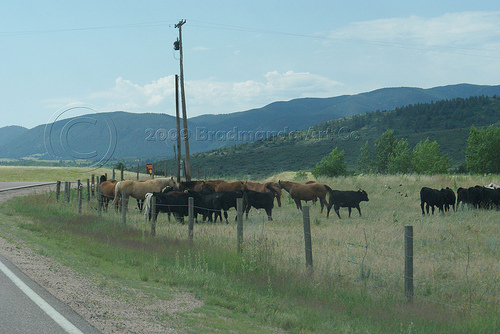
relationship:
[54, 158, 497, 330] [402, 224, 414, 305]
fence has pole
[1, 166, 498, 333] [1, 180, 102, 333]
grass next to road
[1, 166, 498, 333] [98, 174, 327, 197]
pasture has horse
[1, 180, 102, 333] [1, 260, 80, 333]
road has mark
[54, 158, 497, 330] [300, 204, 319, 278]
fence has wood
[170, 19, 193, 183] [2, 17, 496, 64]
post has wire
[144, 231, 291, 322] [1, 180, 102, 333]
plants next road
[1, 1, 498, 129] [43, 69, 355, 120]
sky has cloud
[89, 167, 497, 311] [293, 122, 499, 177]
pasture has trees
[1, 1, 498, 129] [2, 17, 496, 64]
sky has wire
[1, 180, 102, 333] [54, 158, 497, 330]
road next to field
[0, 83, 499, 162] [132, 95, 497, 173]
mountains has trees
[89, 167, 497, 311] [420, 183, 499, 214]
pasture has cows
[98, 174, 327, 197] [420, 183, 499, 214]
horse next to cows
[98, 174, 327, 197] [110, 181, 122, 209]
horse has tail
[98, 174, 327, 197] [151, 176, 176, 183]
horse has mane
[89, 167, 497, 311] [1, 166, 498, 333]
pasture has grass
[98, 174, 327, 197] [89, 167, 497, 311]
horse in pasture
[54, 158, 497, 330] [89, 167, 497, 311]
fence next to pasture